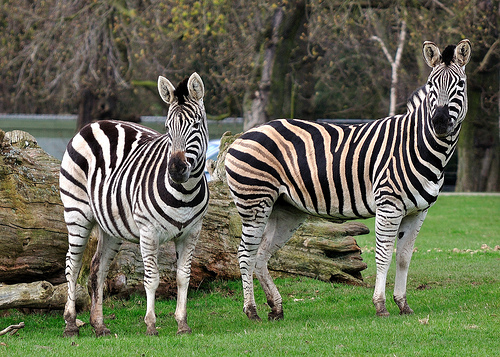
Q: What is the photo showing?
A: It is showing a forest.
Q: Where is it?
A: This is at the forest.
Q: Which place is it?
A: It is a forest.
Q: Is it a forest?
A: Yes, it is a forest.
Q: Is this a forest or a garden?
A: It is a forest.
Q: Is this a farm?
A: No, it is a forest.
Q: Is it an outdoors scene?
A: Yes, it is outdoors.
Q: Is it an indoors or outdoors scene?
A: It is outdoors.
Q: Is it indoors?
A: No, it is outdoors.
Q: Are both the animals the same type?
A: Yes, all the animals are zebras.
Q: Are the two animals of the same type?
A: Yes, all the animals are zebras.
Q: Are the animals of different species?
A: No, all the animals are zebras.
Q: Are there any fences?
A: No, there are no fences.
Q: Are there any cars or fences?
A: No, there are no fences or cars.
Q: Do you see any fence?
A: No, there are no fences.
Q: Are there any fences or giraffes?
A: No, there are no fences or giraffes.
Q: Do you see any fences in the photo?
A: No, there are no fences.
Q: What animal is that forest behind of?
A: The forest is behind the zebra.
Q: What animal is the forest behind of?
A: The forest is behind the zebra.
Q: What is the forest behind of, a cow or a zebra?
A: The forest is behind a zebra.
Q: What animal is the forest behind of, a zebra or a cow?
A: The forest is behind a zebra.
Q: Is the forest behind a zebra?
A: Yes, the forest is behind a zebra.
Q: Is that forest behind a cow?
A: No, the forest is behind a zebra.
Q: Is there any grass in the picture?
A: Yes, there is grass.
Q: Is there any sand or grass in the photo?
A: Yes, there is grass.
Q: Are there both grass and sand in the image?
A: No, there is grass but no sand.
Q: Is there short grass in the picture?
A: Yes, there is short grass.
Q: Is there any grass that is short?
A: Yes, there is grass that is short.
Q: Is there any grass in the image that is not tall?
A: Yes, there is short grass.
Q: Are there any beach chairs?
A: No, there are no beach chairs.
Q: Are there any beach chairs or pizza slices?
A: No, there are no beach chairs or pizza slices.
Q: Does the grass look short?
A: Yes, the grass is short.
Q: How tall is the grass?
A: The grass is short.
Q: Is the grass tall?
A: No, the grass is short.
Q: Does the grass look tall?
A: No, the grass is short.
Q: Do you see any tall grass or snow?
A: No, there is grass but it is short.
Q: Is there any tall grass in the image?
A: No, there is grass but it is short.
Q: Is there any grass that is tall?
A: No, there is grass but it is short.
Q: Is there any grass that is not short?
A: No, there is grass but it is short.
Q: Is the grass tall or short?
A: The grass is short.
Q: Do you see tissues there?
A: No, there are no tissues.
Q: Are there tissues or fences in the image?
A: No, there are no tissues or fences.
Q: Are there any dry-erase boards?
A: No, there are no dry-erase boards.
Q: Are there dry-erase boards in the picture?
A: No, there are no dry-erase boards.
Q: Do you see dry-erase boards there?
A: No, there are no dry-erase boards.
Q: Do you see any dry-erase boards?
A: No, there are no dry-erase boards.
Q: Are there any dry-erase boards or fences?
A: No, there are no dry-erase boards or fences.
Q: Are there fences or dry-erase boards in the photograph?
A: No, there are no dry-erase boards or fences.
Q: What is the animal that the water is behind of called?
A: The animal is a zebra.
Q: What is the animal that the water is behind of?
A: The animal is a zebra.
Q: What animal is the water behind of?
A: The water is behind the zebra.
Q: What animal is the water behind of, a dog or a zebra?
A: The water is behind a zebra.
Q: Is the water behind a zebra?
A: Yes, the water is behind a zebra.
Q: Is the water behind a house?
A: No, the water is behind a zebra.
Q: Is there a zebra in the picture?
A: Yes, there is a zebra.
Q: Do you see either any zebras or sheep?
A: Yes, there is a zebra.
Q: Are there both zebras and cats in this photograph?
A: No, there is a zebra but no cats.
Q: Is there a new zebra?
A: Yes, there is a new zebra.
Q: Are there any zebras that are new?
A: Yes, there is a zebra that is new.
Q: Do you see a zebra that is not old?
A: Yes, there is an new zebra.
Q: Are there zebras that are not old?
A: Yes, there is an new zebra.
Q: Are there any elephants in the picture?
A: No, there are no elephants.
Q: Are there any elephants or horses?
A: No, there are no elephants or horses.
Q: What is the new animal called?
A: The animal is a zebra.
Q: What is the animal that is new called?
A: The animal is a zebra.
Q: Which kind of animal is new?
A: The animal is a zebra.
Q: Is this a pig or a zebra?
A: This is a zebra.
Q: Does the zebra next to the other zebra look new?
A: Yes, the zebra is new.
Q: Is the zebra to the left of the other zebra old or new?
A: The zebra is new.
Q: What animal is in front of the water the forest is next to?
A: The zebra is in front of the water.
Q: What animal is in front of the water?
A: The zebra is in front of the water.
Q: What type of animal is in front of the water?
A: The animal is a zebra.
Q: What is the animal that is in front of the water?
A: The animal is a zebra.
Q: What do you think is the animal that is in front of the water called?
A: The animal is a zebra.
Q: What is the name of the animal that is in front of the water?
A: The animal is a zebra.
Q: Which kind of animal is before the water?
A: The animal is a zebra.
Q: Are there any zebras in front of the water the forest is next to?
A: Yes, there is a zebra in front of the water.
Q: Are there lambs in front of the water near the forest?
A: No, there is a zebra in front of the water.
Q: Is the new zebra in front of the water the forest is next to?
A: Yes, the zebra is in front of the water.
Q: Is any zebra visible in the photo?
A: Yes, there is a zebra.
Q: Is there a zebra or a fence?
A: Yes, there is a zebra.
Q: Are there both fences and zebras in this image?
A: No, there is a zebra but no fences.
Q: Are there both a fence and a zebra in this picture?
A: No, there is a zebra but no fences.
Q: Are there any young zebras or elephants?
A: Yes, there is a young zebra.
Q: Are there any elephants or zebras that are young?
A: Yes, the zebra is young.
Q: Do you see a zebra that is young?
A: Yes, there is a young zebra.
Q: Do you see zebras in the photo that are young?
A: Yes, there is a zebra that is young.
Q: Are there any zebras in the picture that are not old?
A: Yes, there is an young zebra.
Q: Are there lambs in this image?
A: No, there are no lambs.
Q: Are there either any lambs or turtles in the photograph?
A: No, there are no lambs or turtles.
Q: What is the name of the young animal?
A: The animal is a zebra.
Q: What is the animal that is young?
A: The animal is a zebra.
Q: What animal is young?
A: The animal is a zebra.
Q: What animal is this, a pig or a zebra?
A: This is a zebra.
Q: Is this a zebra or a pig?
A: This is a zebra.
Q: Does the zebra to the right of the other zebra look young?
A: Yes, the zebra is young.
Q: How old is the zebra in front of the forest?
A: The zebra is young.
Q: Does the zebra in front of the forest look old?
A: No, the zebra is young.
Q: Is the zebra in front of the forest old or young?
A: The zebra is young.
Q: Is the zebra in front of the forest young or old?
A: The zebra is young.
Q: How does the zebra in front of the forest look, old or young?
A: The zebra is young.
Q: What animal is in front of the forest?
A: The zebra is in front of the forest.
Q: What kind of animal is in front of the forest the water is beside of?
A: The animal is a zebra.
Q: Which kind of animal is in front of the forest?
A: The animal is a zebra.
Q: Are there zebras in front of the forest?
A: Yes, there is a zebra in front of the forest.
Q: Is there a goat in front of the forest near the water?
A: No, there is a zebra in front of the forest.